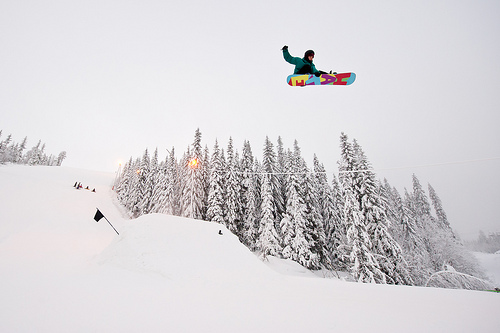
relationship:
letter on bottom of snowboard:
[333, 74, 348, 85] [285, 70, 357, 87]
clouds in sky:
[0, 0, 500, 164] [0, 0, 277, 145]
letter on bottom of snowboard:
[333, 72, 351, 85] [283, 67, 354, 92]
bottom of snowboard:
[286, 72, 355, 87] [277, 54, 412, 125]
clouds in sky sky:
[0, 0, 500, 164] [16, 7, 496, 254]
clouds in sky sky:
[306, 90, 488, 138] [16, 7, 496, 254]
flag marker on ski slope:
[90, 207, 121, 236] [0, 160, 497, 327]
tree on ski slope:
[207, 134, 226, 225] [0, 160, 497, 327]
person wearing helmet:
[281, 44, 339, 76] [303, 50, 315, 58]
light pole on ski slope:
[177, 155, 204, 233] [98, 172, 318, 324]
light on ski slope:
[189, 157, 197, 217] [0, 160, 497, 327]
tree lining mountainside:
[207, 134, 226, 225] [2, 162, 499, 331]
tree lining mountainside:
[277, 148, 322, 267] [2, 162, 499, 331]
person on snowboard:
[283, 44, 337, 74] [288, 72, 355, 84]